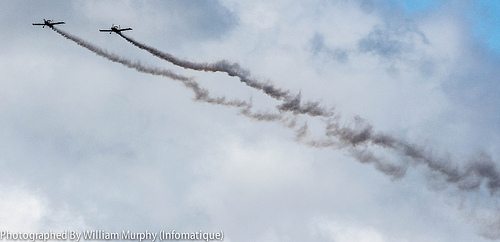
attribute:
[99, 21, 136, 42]
plane — flying, smoking, small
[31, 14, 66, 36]
plane — flying, smoking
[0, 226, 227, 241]
tag — photographer, white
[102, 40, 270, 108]
smoke — grey, black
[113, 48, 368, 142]
vapor trails — dark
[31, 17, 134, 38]
planes — together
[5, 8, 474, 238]
sky — cloudy, stormy, blue, white, grey, dark grey